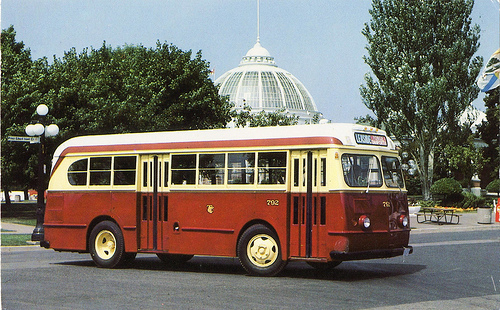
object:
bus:
[40, 122, 416, 279]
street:
[0, 226, 498, 309]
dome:
[206, 0, 331, 117]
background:
[1, 1, 500, 124]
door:
[135, 152, 170, 252]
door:
[286, 148, 326, 261]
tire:
[87, 219, 139, 269]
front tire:
[236, 222, 289, 277]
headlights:
[356, 214, 372, 230]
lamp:
[34, 103, 51, 117]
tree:
[41, 38, 234, 185]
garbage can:
[474, 206, 493, 224]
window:
[340, 153, 385, 188]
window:
[171, 154, 199, 185]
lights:
[32, 123, 46, 137]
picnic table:
[415, 205, 460, 225]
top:
[236, 0, 280, 67]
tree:
[355, 1, 483, 207]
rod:
[254, 1, 260, 44]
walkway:
[1, 221, 44, 235]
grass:
[3, 230, 29, 245]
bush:
[427, 176, 465, 207]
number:
[266, 200, 281, 205]